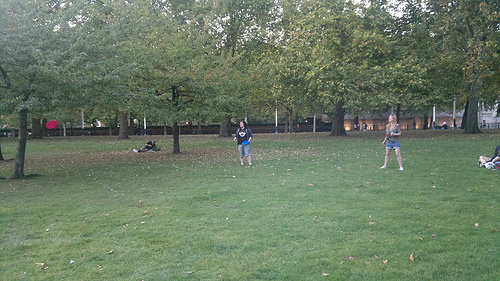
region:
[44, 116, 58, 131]
red frisbee flying through air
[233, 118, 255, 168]
woman holding blue frisbee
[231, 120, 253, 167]
woman standing on grass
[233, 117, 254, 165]
woman wearing black top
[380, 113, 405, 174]
woman standing outside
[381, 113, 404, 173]
woman wearing denim shorts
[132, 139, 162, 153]
person laying on grass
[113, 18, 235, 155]
green tree on field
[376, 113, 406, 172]
woman playing with frisbee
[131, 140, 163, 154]
person laying under tree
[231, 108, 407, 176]
Two girls are in a park.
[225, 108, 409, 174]
Two girls are wearing shorts.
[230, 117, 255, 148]
A girl is wearing a dark jacket.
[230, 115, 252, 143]
A girl is wearing a black and white top.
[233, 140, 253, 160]
A girl is wearing dark shorts.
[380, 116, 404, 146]
A girl is wearing a green top.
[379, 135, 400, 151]
A girl is wearing blue shorts.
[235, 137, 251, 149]
A girl is holding a frisbee.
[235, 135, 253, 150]
The color of a frisbee is blue.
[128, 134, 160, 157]
A person is behind two girls.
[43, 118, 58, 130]
a red frisbee in the air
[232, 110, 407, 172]
two people playing frisbee in a park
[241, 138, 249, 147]
a blue frisbee in the person's left hand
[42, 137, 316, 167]
a circle of leaves on the ground around the tree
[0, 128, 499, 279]
a field of grass in the middle of a park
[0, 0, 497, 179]
a bunch of trees in the park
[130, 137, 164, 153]
a person laying on the grass underneath a tree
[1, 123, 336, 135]
a long brown fence behind the trees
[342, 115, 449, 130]
lights from a building behind the trees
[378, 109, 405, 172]
a girl with blonde hair standing in the field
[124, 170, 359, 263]
patch of green grass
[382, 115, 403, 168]
girl with shorts standing on grass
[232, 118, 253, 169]
girl with capris standing on grass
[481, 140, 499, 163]
people sitting on grass with their belongings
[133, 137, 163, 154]
people laying on grass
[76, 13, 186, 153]
people laying under tree that's giving off shade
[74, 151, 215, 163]
fallen leaves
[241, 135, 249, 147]
frisbee in hand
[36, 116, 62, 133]
second frisbee flying in air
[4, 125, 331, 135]
fenced off area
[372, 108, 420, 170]
lady standing in a field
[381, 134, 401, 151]
woman wearing blue jeans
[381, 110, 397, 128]
woman with blonde hair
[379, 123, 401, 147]
woman with a brown shirt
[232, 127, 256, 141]
woman with a black shirt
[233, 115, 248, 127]
woman with black hair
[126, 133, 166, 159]
man sitting in the park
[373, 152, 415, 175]
woman wearing white shoes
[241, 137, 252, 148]
woman holding a Frisbee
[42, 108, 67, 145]
Red Frisbee in the sky